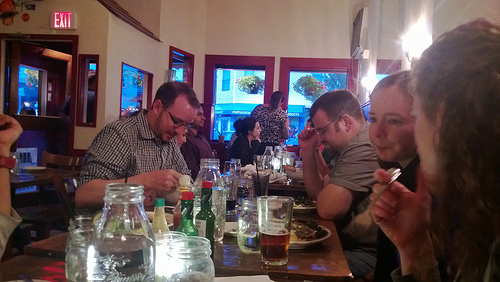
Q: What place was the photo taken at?
A: It was taken at the restaurant.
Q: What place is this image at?
A: It is at the restaurant.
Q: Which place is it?
A: It is a restaurant.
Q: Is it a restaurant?
A: Yes, it is a restaurant.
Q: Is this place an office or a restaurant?
A: It is a restaurant.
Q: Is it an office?
A: No, it is a restaurant.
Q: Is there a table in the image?
A: Yes, there is a table.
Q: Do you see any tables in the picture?
A: Yes, there is a table.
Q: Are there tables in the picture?
A: Yes, there is a table.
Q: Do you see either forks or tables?
A: Yes, there is a table.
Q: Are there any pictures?
A: No, there are no pictures.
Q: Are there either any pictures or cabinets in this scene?
A: No, there are no pictures or cabinets.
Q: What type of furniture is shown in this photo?
A: The furniture is a table.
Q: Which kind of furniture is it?
A: The piece of furniture is a table.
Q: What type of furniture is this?
A: This is a table.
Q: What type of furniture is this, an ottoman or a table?
A: This is a table.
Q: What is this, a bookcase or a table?
A: This is a table.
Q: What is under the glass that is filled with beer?
A: The table is under the glass.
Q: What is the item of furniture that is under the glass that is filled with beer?
A: The piece of furniture is a table.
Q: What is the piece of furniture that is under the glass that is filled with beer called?
A: The piece of furniture is a table.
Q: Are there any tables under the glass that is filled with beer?
A: Yes, there is a table under the glass.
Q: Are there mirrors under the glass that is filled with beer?
A: No, there is a table under the glass.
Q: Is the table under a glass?
A: Yes, the table is under a glass.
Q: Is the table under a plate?
A: No, the table is under a glass.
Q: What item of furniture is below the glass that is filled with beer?
A: The piece of furniture is a table.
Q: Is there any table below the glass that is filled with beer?
A: Yes, there is a table below the glass.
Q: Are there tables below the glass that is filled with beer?
A: Yes, there is a table below the glass.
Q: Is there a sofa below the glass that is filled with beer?
A: No, there is a table below the glass.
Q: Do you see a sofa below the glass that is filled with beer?
A: No, there is a table below the glass.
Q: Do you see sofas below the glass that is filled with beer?
A: No, there is a table below the glass.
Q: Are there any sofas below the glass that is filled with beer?
A: No, there is a table below the glass.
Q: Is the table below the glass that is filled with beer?
A: Yes, the table is below the glass.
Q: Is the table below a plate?
A: No, the table is below the glass.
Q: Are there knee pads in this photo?
A: No, there are no knee pads.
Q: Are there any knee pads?
A: No, there are no knee pads.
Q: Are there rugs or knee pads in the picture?
A: No, there are no knee pads or rugs.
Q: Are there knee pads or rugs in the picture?
A: No, there are no knee pads or rugs.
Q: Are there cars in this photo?
A: No, there are no cars.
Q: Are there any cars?
A: No, there are no cars.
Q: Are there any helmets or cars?
A: No, there are no cars or helmets.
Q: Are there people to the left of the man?
A: Yes, there is a person to the left of the man.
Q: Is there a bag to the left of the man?
A: No, there is a person to the left of the man.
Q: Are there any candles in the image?
A: No, there are no candles.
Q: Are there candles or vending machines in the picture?
A: No, there are no candles or vending machines.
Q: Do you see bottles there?
A: Yes, there is a bottle.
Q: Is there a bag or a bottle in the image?
A: Yes, there is a bottle.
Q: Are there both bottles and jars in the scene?
A: Yes, there are both a bottle and jars.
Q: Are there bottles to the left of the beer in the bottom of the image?
A: Yes, there is a bottle to the left of the beer.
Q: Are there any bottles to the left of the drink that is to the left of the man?
A: Yes, there is a bottle to the left of the beer.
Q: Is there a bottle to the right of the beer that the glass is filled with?
A: No, the bottle is to the left of the beer.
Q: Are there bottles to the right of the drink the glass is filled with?
A: No, the bottle is to the left of the beer.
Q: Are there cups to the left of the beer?
A: No, there is a bottle to the left of the beer.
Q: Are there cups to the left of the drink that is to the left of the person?
A: No, there is a bottle to the left of the beer.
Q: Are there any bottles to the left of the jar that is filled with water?
A: Yes, there is a bottle to the left of the jar.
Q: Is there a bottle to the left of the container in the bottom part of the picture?
A: Yes, there is a bottle to the left of the jar.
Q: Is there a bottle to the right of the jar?
A: No, the bottle is to the left of the jar.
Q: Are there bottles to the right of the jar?
A: No, the bottle is to the left of the jar.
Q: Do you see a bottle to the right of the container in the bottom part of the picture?
A: No, the bottle is to the left of the jar.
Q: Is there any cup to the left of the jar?
A: No, there is a bottle to the left of the jar.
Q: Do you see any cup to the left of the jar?
A: No, there is a bottle to the left of the jar.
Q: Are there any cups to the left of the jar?
A: No, there is a bottle to the left of the jar.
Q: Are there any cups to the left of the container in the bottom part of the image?
A: No, there is a bottle to the left of the jar.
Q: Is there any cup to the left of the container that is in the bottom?
A: No, there is a bottle to the left of the jar.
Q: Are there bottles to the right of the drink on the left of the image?
A: Yes, there is a bottle to the right of the drink.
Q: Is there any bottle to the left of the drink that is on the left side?
A: No, the bottle is to the right of the drink.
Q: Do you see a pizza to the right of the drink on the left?
A: No, there is a bottle to the right of the drink.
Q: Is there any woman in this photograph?
A: Yes, there is a woman.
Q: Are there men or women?
A: Yes, there is a woman.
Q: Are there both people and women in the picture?
A: Yes, there are both a woman and people.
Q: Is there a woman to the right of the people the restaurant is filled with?
A: Yes, there is a woman to the right of the people.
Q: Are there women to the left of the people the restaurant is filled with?
A: No, the woman is to the right of the people.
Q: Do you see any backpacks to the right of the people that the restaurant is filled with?
A: No, there is a woman to the right of the people.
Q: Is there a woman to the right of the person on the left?
A: Yes, there is a woman to the right of the person.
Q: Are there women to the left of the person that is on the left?
A: No, the woman is to the right of the person.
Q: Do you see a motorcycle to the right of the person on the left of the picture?
A: No, there is a woman to the right of the person.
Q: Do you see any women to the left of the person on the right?
A: Yes, there is a woman to the left of the person.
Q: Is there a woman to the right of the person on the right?
A: No, the woman is to the left of the person.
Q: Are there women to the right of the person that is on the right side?
A: No, the woman is to the left of the person.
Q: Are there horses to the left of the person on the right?
A: No, there is a woman to the left of the person.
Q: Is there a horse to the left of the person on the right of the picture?
A: No, there is a woman to the left of the person.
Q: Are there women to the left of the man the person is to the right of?
A: Yes, there is a woman to the left of the man.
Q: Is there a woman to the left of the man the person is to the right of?
A: Yes, there is a woman to the left of the man.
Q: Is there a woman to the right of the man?
A: No, the woman is to the left of the man.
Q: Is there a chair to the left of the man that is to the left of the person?
A: No, there is a woman to the left of the man.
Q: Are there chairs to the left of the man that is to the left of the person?
A: No, there is a woman to the left of the man.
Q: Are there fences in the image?
A: No, there are no fences.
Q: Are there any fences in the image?
A: No, there are no fences.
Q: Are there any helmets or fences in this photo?
A: No, there are no fences or helmets.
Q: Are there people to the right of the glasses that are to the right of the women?
A: Yes, there is a person to the right of the glasses.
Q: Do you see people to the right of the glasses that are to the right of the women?
A: Yes, there is a person to the right of the glasses.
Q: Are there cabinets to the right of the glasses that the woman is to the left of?
A: No, there is a person to the right of the glasses.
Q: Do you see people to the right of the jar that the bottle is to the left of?
A: Yes, there is a person to the right of the jar.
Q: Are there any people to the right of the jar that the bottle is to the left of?
A: Yes, there is a person to the right of the jar.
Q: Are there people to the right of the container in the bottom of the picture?
A: Yes, there is a person to the right of the jar.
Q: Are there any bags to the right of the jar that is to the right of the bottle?
A: No, there is a person to the right of the jar.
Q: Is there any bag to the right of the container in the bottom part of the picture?
A: No, there is a person to the right of the jar.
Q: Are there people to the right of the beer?
A: Yes, there is a person to the right of the beer.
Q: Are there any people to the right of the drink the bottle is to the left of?
A: Yes, there is a person to the right of the beer.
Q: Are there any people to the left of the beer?
A: No, the person is to the right of the beer.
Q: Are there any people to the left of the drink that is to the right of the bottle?
A: No, the person is to the right of the beer.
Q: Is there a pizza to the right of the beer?
A: No, there is a person to the right of the beer.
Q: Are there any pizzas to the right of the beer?
A: No, there is a person to the right of the beer.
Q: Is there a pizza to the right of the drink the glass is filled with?
A: No, there is a person to the right of the beer.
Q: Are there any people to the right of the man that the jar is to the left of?
A: Yes, there is a person to the right of the man.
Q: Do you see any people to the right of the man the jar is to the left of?
A: Yes, there is a person to the right of the man.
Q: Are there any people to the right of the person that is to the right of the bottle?
A: Yes, there is a person to the right of the man.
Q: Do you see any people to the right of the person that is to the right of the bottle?
A: Yes, there is a person to the right of the man.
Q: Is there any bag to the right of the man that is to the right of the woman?
A: No, there is a person to the right of the man.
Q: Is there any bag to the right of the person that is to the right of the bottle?
A: No, there is a person to the right of the man.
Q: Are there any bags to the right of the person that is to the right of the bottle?
A: No, there is a person to the right of the man.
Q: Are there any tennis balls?
A: No, there are no tennis balls.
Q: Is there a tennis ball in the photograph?
A: No, there are no tennis balls.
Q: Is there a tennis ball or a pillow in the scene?
A: No, there are no tennis balls or pillows.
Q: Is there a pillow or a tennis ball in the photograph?
A: No, there are no tennis balls or pillows.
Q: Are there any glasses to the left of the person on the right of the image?
A: Yes, there are glasses to the left of the person.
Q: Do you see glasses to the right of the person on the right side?
A: No, the glasses are to the left of the person.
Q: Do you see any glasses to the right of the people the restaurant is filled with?
A: Yes, there are glasses to the right of the people.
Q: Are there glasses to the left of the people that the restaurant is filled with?
A: No, the glasses are to the right of the people.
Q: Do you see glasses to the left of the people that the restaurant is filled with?
A: No, the glasses are to the right of the people.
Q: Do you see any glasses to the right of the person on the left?
A: Yes, there are glasses to the right of the person.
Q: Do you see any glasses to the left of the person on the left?
A: No, the glasses are to the right of the person.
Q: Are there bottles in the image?
A: Yes, there is a bottle.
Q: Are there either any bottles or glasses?
A: Yes, there is a bottle.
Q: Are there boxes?
A: No, there are no boxes.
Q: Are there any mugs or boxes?
A: No, there are no boxes or mugs.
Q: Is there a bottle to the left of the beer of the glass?
A: Yes, there is a bottle to the left of the beer.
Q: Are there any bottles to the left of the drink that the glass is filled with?
A: Yes, there is a bottle to the left of the beer.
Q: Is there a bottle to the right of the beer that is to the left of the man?
A: No, the bottle is to the left of the beer.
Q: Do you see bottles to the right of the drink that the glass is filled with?
A: No, the bottle is to the left of the beer.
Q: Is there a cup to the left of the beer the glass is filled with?
A: No, there is a bottle to the left of the beer.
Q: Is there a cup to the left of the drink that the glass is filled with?
A: No, there is a bottle to the left of the beer.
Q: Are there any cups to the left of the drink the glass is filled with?
A: No, there is a bottle to the left of the beer.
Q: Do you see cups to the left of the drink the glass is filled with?
A: No, there is a bottle to the left of the beer.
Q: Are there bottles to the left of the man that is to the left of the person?
A: Yes, there is a bottle to the left of the man.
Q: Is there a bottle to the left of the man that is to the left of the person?
A: Yes, there is a bottle to the left of the man.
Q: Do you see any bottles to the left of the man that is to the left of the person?
A: Yes, there is a bottle to the left of the man.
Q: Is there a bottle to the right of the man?
A: No, the bottle is to the left of the man.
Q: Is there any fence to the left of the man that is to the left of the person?
A: No, there is a bottle to the left of the man.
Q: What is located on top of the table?
A: The bottle is on top of the table.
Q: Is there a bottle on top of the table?
A: Yes, there is a bottle on top of the table.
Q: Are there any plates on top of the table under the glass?
A: No, there is a bottle on top of the table.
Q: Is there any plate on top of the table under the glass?
A: No, there is a bottle on top of the table.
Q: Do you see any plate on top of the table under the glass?
A: No, there is a bottle on top of the table.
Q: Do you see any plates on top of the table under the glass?
A: No, there is a bottle on top of the table.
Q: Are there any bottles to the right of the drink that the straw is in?
A: Yes, there is a bottle to the right of the drink.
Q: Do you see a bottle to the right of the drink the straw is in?
A: Yes, there is a bottle to the right of the drink.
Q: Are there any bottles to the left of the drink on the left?
A: No, the bottle is to the right of the drink.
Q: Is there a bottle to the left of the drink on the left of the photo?
A: No, the bottle is to the right of the drink.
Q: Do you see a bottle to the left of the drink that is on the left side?
A: No, the bottle is to the right of the drink.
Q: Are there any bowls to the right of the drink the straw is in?
A: No, there is a bottle to the right of the drink.